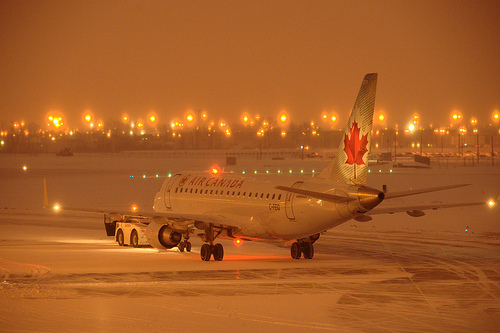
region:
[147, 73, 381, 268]
Aeroplane in an airport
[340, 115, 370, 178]
Flower on plane's tail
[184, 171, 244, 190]
Red writing on plane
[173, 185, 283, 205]
Small windows on plane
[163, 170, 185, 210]
Door on the side of plane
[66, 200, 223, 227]
Left wing of plane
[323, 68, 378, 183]
Tail of a plane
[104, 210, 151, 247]
Car in front of plane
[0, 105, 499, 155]
Lights in the background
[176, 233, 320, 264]
Six wheels of plane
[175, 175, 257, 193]
name on side of plane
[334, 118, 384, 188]
red leaf on tail of plane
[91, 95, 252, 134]
bright lights in the vista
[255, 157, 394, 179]
lights on the runway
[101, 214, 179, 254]
white vehicle under plane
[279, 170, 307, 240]
door on side of plane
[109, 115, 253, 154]
houses in the far distance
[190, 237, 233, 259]
black wheels under plane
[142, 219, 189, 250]
wing on side of plane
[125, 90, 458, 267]
large passenger plane on the tarmac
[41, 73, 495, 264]
an airplane on tarmac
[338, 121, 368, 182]
a red maple leaf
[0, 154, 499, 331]
a snowy airport tarmac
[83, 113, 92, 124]
an overhead light in distance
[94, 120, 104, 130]
an overhead light in distance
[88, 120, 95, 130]
an overhead light in distance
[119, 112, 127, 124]
an overhead light in distance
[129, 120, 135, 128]
an overhead light in distance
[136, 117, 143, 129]
an overhead light in distance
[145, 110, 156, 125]
an overhead light in distance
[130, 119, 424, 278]
Airplane on a snowy reway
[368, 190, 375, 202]
back of a plane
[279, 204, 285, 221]
part of a plane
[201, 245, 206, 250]
part of a wheel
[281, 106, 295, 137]
part of a light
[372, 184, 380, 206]
tip of a plane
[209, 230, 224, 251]
part of a wheel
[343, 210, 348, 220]
back of a plane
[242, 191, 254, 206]
side of a plane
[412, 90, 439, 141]
part of a light